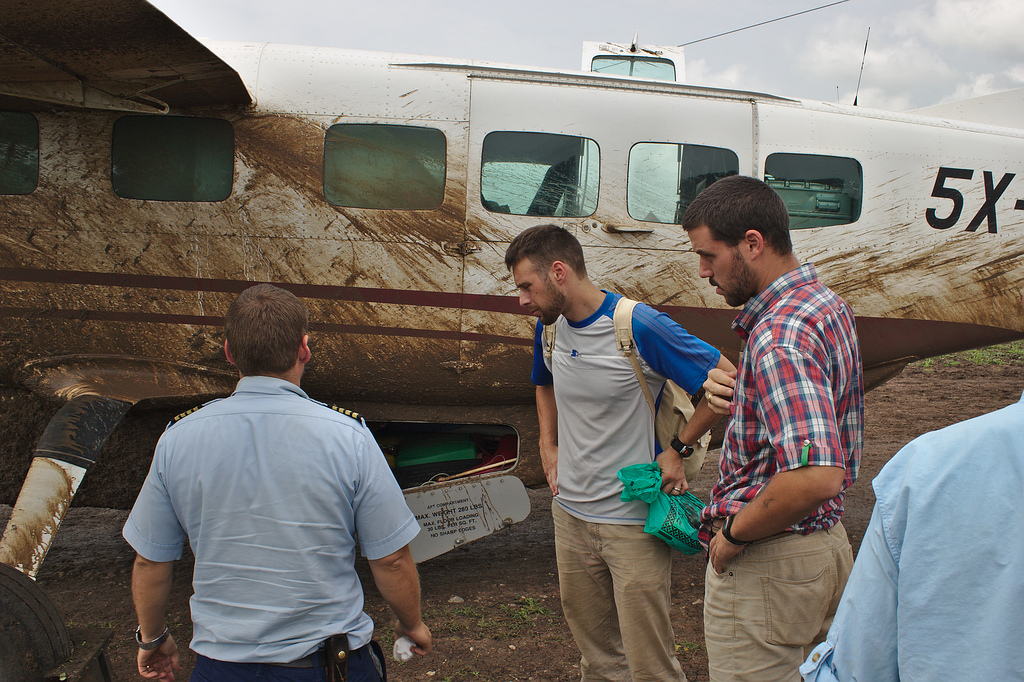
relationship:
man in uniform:
[110, 281, 437, 670] [108, 370, 422, 664]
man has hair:
[110, 281, 437, 670] [218, 269, 309, 378]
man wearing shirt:
[587, 156, 823, 429] [678, 284, 882, 526]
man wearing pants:
[674, 171, 868, 681] [682, 480, 883, 664]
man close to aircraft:
[506, 223, 738, 679] [1, 8, 1006, 462]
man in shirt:
[505, 223, 737, 679] [527, 288, 722, 526]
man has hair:
[505, 223, 737, 679] [505, 225, 586, 278]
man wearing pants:
[505, 223, 737, 679] [551, 502, 688, 677]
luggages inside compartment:
[378, 428, 484, 470] [371, 420, 519, 488]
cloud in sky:
[693, 7, 989, 120] [153, 1, 988, 122]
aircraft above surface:
[2, 0, 1024, 576] [6, 348, 990, 677]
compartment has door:
[371, 420, 519, 488] [402, 471, 534, 564]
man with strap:
[505, 223, 737, 679] [540, 325, 558, 373]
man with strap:
[505, 223, 737, 679] [613, 294, 659, 418]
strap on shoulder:
[540, 325, 558, 373] [531, 318, 555, 342]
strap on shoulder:
[613, 294, 659, 418] [605, 290, 651, 340]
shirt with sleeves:
[698, 260, 863, 542] [752, 344, 846, 468]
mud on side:
[15, 111, 986, 487] [0, 93, 992, 415]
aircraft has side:
[2, 0, 1024, 576] [0, 93, 992, 415]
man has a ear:
[506, 223, 738, 679] [547, 256, 569, 285]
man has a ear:
[674, 171, 868, 681] [744, 221, 768, 263]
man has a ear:
[117, 281, 443, 681] [299, 329, 313, 356]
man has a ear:
[117, 281, 443, 681] [219, 327, 233, 375]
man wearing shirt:
[505, 223, 737, 679] [527, 288, 722, 526]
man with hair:
[505, 223, 737, 679] [506, 221, 586, 280]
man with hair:
[506, 223, 738, 679] [526, 277, 561, 323]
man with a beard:
[505, 223, 737, 679] [532, 275, 565, 319]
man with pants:
[506, 223, 738, 679] [545, 500, 679, 656]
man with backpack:
[506, 223, 738, 679] [642, 385, 725, 461]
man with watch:
[506, 223, 738, 679] [668, 424, 697, 459]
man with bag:
[505, 223, 737, 679] [614, 461, 707, 556]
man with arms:
[505, 223, 737, 679] [638, 305, 742, 472]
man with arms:
[505, 223, 737, 679] [525, 323, 562, 484]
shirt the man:
[698, 260, 863, 542] [675, 169, 863, 660]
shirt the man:
[527, 288, 722, 526] [506, 223, 738, 679]